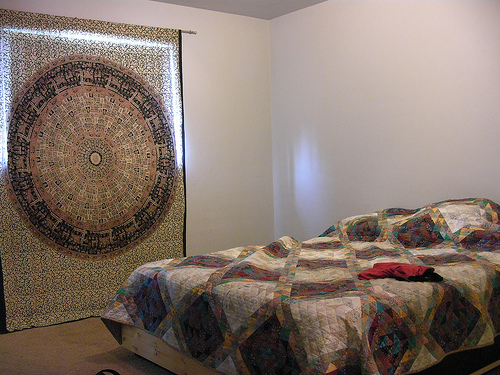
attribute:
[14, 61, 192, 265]
pattern — circular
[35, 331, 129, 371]
floor — beige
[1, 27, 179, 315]
shade — long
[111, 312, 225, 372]
bed frame — wooden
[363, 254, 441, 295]
garment — red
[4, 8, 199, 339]
curtain — long , brown, window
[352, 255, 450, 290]
shirt — red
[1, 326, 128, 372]
floor — carpeted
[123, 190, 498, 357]
bed — made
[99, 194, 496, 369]
blanket — multi-colored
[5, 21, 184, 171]
sun — bright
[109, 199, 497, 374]
bed — large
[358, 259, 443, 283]
cloth — red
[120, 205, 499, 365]
comforter — dark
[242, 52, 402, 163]
walls — white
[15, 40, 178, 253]
curtain — closed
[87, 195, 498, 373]
cover — bed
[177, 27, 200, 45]
rod — curtain